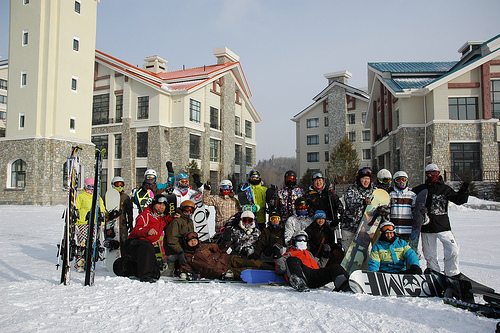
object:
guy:
[410, 163, 473, 280]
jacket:
[410, 176, 473, 234]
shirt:
[387, 186, 417, 234]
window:
[210, 134, 221, 161]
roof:
[363, 32, 498, 92]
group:
[73, 163, 479, 295]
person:
[304, 172, 345, 222]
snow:
[3, 193, 498, 331]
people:
[238, 169, 268, 229]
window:
[306, 152, 319, 163]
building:
[0, 0, 264, 206]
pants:
[420, 230, 459, 276]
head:
[153, 194, 169, 212]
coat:
[177, 244, 231, 278]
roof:
[184, 48, 265, 97]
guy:
[113, 194, 181, 282]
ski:
[56, 144, 105, 288]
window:
[307, 118, 320, 129]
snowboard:
[240, 268, 286, 284]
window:
[448, 97, 483, 121]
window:
[306, 134, 318, 146]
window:
[184, 95, 203, 124]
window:
[307, 134, 323, 152]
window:
[7, 158, 26, 189]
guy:
[181, 231, 287, 282]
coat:
[367, 237, 420, 273]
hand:
[147, 228, 158, 235]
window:
[242, 146, 254, 166]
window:
[245, 119, 253, 142]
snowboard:
[347, 270, 454, 299]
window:
[244, 119, 253, 139]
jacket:
[275, 248, 330, 282]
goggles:
[395, 177, 408, 183]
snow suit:
[127, 203, 175, 242]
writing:
[363, 270, 439, 294]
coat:
[75, 190, 105, 228]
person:
[68, 178, 106, 272]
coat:
[127, 205, 175, 247]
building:
[290, 34, 500, 187]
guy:
[389, 170, 417, 240]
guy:
[365, 221, 423, 275]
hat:
[152, 194, 169, 206]